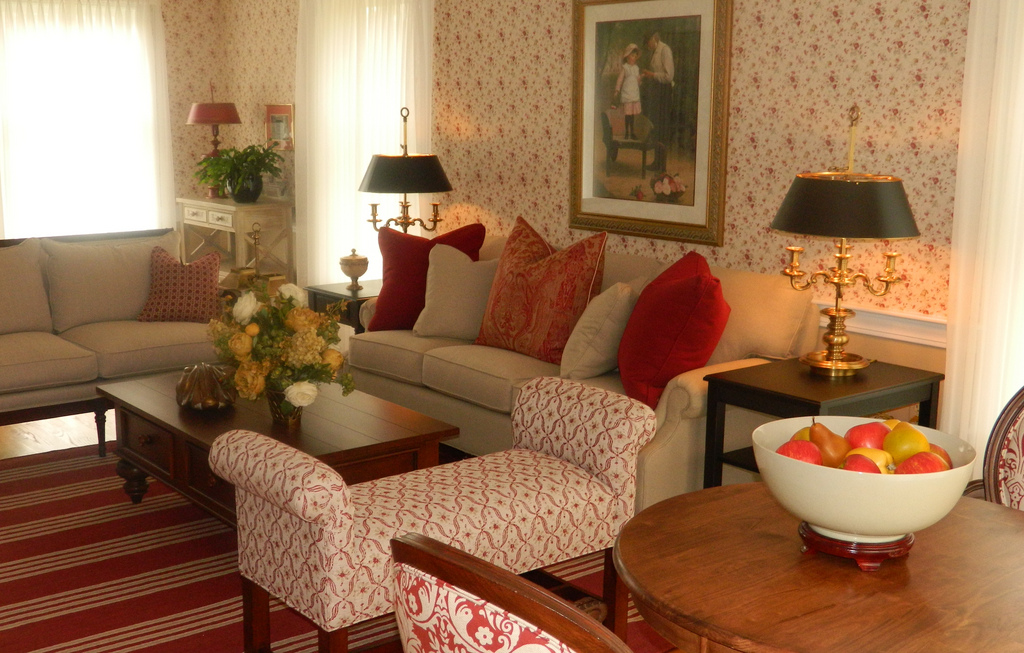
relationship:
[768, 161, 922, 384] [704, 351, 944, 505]
lamp on table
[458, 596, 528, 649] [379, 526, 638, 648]
design on chair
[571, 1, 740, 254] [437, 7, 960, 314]
picture on wall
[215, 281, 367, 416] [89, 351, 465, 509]
bouquet on top of table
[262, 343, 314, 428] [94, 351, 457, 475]
vase on table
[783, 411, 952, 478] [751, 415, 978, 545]
fruits inside bowl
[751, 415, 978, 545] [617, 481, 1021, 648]
bowl on top of table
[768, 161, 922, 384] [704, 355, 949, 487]
lamp on top of table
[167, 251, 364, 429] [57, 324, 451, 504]
arrangement on top of table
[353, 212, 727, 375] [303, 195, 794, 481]
pillows are on top of sofa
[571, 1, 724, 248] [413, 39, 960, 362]
picture hanging on wall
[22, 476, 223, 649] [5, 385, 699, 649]
rug on top of floor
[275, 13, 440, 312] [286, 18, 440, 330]
curtain hanging from window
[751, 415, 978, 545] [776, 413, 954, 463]
bowl holding fruits